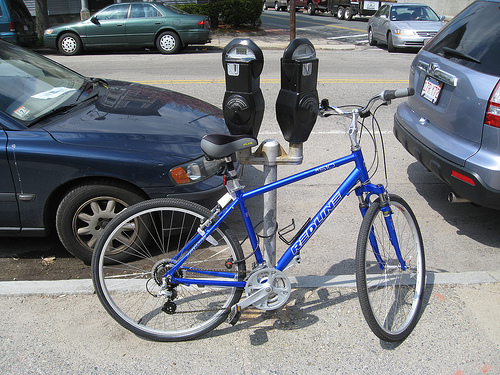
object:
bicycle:
[90, 87, 425, 341]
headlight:
[394, 29, 415, 36]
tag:
[420, 75, 445, 105]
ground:
[0, 0, 500, 375]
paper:
[30, 87, 77, 100]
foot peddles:
[226, 285, 272, 327]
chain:
[230, 220, 278, 265]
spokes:
[366, 207, 424, 329]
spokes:
[102, 208, 237, 336]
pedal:
[227, 286, 274, 328]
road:
[0, 0, 499, 375]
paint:
[131, 76, 412, 85]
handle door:
[116, 24, 123, 27]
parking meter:
[221, 36, 263, 138]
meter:
[274, 37, 319, 156]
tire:
[55, 179, 150, 266]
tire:
[156, 31, 182, 54]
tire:
[57, 31, 82, 56]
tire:
[368, 31, 377, 47]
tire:
[387, 31, 395, 52]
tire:
[355, 193, 427, 342]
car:
[0, 37, 245, 266]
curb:
[0, 269, 498, 301]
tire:
[90, 197, 248, 343]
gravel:
[0, 283, 500, 375]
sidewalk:
[0, 267, 500, 375]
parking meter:
[272, 36, 321, 151]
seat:
[200, 133, 259, 159]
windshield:
[0, 42, 84, 129]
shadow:
[198, 257, 374, 346]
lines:
[127, 79, 412, 84]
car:
[43, 2, 214, 57]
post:
[238, 138, 305, 269]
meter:
[221, 36, 266, 165]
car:
[391, 0, 500, 212]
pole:
[259, 140, 280, 269]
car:
[367, 3, 450, 54]